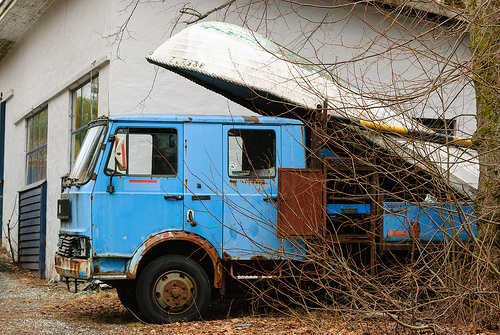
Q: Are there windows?
A: Yes, there is a window.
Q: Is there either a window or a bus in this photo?
A: Yes, there is a window.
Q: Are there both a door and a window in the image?
A: Yes, there are both a window and a door.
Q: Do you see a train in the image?
A: No, there are no trains.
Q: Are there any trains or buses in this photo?
A: No, there are no trains or buses.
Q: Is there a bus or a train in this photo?
A: No, there are no trains or buses.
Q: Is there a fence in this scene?
A: No, there are no fences.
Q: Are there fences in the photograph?
A: No, there are no fences.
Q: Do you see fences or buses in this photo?
A: No, there are no fences or buses.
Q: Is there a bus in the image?
A: No, there are no buses.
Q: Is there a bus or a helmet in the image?
A: No, there are no buses or helmets.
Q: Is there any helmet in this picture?
A: No, there are no helmets.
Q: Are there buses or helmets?
A: No, there are no helmets or buses.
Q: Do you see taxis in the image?
A: Yes, there is a taxi.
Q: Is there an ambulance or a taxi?
A: Yes, there is a taxi.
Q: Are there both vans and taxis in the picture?
A: No, there is a taxi but no vans.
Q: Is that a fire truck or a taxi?
A: That is a taxi.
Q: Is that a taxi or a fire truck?
A: That is a taxi.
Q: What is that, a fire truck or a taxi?
A: That is a taxi.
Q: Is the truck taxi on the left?
A: Yes, the taxi is on the left of the image.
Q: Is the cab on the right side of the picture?
A: No, the cab is on the left of the image.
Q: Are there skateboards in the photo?
A: No, there are no skateboards.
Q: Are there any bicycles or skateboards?
A: No, there are no skateboards or bicycles.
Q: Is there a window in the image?
A: Yes, there is a window.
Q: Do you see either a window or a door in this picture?
A: Yes, there is a window.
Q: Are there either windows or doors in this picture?
A: Yes, there is a window.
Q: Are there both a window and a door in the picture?
A: Yes, there are both a window and a door.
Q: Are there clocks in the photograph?
A: No, there are no clocks.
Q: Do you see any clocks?
A: No, there are no clocks.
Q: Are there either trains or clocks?
A: No, there are no clocks or trains.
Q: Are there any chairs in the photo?
A: No, there are no chairs.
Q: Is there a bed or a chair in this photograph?
A: No, there are no chairs or beds.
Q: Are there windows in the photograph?
A: Yes, there is a window.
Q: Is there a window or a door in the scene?
A: Yes, there is a window.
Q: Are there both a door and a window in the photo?
A: Yes, there are both a window and a door.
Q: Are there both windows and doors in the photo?
A: Yes, there are both a window and a door.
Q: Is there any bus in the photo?
A: No, there are no buses.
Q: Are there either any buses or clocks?
A: No, there are no buses or clocks.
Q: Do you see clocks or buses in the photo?
A: No, there are no buses or clocks.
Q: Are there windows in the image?
A: Yes, there is a window.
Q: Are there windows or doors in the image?
A: Yes, there is a window.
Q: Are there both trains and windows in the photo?
A: No, there is a window but no trains.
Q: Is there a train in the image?
A: No, there are no trains.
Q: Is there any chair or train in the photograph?
A: No, there are no trains or chairs.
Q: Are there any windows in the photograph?
A: Yes, there is a window.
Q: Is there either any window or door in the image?
A: Yes, there is a window.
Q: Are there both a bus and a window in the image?
A: No, there is a window but no buses.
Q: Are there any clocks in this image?
A: No, there are no clocks.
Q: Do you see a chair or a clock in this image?
A: No, there are no clocks or chairs.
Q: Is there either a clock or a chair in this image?
A: No, there are no clocks or chairs.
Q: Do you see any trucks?
A: Yes, there is a truck.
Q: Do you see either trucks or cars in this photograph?
A: Yes, there is a truck.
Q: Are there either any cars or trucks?
A: Yes, there is a truck.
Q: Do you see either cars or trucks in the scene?
A: Yes, there is a truck.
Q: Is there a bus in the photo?
A: No, there are no buses.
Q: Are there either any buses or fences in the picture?
A: No, there are no buses or fences.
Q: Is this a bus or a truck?
A: This is a truck.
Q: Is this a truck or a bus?
A: This is a truck.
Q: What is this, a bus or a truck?
A: This is a truck.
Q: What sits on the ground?
A: The truck sits on the ground.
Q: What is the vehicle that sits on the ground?
A: The vehicle is a truck.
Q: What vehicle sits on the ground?
A: The vehicle is a truck.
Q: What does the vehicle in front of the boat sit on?
A: The truck sits on the ground.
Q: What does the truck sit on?
A: The truck sits on the ground.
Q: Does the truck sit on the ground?
A: Yes, the truck sits on the ground.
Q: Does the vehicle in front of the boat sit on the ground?
A: Yes, the truck sits on the ground.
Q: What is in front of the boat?
A: The truck is in front of the boat.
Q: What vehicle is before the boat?
A: The vehicle is a truck.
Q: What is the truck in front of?
A: The truck is in front of the boat.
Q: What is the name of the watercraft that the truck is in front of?
A: The watercraft is a boat.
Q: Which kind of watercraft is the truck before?
A: The truck is in front of the boat.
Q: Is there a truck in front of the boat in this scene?
A: Yes, there is a truck in front of the boat.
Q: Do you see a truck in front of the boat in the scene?
A: Yes, there is a truck in front of the boat.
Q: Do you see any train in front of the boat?
A: No, there is a truck in front of the boat.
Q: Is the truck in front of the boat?
A: Yes, the truck is in front of the boat.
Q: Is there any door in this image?
A: Yes, there is a door.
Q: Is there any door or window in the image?
A: Yes, there is a door.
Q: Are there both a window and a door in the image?
A: Yes, there are both a door and a window.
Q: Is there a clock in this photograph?
A: No, there are no clocks.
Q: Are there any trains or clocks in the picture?
A: No, there are no clocks or trains.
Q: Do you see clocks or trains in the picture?
A: No, there are no clocks or trains.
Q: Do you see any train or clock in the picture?
A: No, there are no clocks or trains.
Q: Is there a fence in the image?
A: No, there are no fences.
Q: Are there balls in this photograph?
A: No, there are no balls.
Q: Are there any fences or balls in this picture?
A: No, there are no balls or fences.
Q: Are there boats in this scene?
A: Yes, there is a boat.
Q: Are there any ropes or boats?
A: Yes, there is a boat.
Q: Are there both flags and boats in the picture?
A: No, there is a boat but no flags.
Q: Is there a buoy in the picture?
A: No, there are no buoys.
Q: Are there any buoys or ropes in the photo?
A: No, there are no buoys or ropes.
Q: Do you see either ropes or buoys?
A: No, there are no buoys or ropes.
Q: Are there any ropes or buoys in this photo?
A: No, there are no buoys or ropes.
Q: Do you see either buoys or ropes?
A: No, there are no buoys or ropes.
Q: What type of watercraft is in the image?
A: The watercraft is a boat.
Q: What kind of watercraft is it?
A: The watercraft is a boat.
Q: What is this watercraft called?
A: This is a boat.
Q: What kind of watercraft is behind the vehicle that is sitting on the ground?
A: The watercraft is a boat.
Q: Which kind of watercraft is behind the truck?
A: The watercraft is a boat.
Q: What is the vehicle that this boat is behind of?
A: The vehicle is a truck.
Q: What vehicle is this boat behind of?
A: The boat is behind the truck.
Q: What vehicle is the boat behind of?
A: The boat is behind the truck.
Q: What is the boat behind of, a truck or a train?
A: The boat is behind a truck.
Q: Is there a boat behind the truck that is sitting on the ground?
A: Yes, there is a boat behind the truck.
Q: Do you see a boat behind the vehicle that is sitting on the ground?
A: Yes, there is a boat behind the truck.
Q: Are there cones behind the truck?
A: No, there is a boat behind the truck.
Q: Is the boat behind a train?
A: No, the boat is behind the truck.